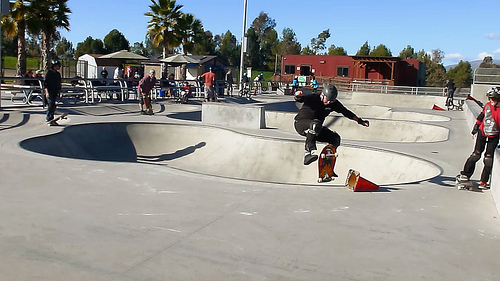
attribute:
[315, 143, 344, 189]
skateboard — orange, red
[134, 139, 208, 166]
shadow — cast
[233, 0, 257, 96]
post — tall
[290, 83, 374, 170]
skater — airborn, skating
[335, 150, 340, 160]
wheel — white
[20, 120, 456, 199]
bowl — for skaters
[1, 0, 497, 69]
sky — clear, blue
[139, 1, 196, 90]
tree — palm, in background, tall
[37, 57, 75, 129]
skater — resting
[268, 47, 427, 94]
building — red, in background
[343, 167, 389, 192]
cone — orange, down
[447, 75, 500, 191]
skater — wearing red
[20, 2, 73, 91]
tree — palm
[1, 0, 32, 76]
tree — palm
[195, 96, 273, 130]
ramp — for skating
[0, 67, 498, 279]
park — for skatboarding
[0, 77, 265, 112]
benches — metal